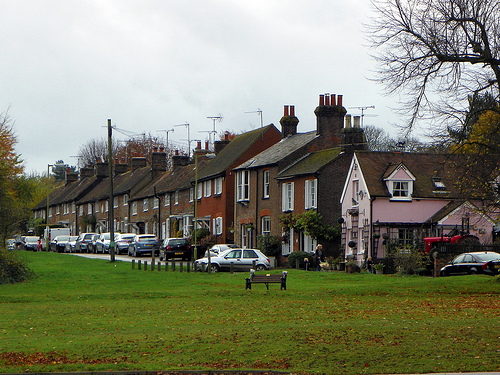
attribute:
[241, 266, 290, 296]
bench — wood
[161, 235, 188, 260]
car — blue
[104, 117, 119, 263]
pole — wooden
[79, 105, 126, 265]
pole — wooden, electrical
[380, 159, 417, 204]
dog-house — Pink 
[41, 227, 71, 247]
van — white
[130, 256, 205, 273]
post — small, wood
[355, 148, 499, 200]
roof — brown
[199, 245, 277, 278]
car — silver, hatch-back, 4 door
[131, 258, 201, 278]
post — wooden, short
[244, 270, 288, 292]
bench — empty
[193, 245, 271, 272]
car — silver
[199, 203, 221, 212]
wall — red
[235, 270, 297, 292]
bench — wood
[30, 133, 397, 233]
houses — brownstone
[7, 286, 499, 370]
grass — green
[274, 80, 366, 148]
chimney — red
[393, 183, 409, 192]
curtains — white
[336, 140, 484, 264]
house — pink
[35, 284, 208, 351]
field — grass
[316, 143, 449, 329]
trim — white